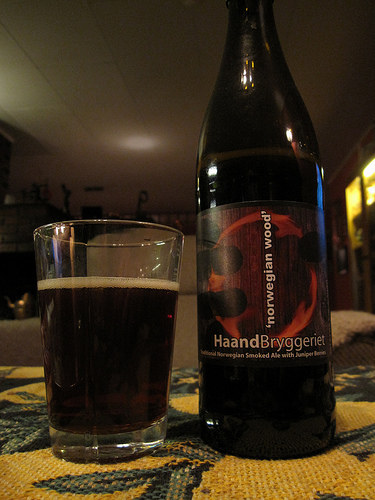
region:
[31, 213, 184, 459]
Clear glass full of ale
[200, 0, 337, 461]
bottle of Norwegian ale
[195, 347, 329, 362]
Traditional Norwegian smoked ale with juniper berries on bottle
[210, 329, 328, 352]
HaandBryggeriet on side of bottle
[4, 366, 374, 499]
floral design on table cover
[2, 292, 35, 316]
tea kettle in background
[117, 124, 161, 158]
glare of light on ceiling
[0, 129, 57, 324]
fireplace in the background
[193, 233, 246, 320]
berry design on bottle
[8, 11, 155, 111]
white ceiling tiles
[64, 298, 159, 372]
Brown liquid in glass.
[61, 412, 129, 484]
Glass sitting on yellow place mat.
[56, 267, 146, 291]
White head on beer.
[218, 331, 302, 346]
White writing on bottle.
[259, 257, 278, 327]
White writing on bottle.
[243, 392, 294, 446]
Dark colored bottle on table.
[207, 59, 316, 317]
Large dark bottle sitting on table.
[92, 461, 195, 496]
Blue coloring on yellow place mat.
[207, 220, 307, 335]
Red coloring on bottle label.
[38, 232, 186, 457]
Clear glass sitting on table.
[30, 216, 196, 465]
dark liquid in a glass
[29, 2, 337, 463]
dark bottle next to the glass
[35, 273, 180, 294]
foam on top of the liquid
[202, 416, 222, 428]
light glare on the bottle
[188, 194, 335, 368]
label around the bottle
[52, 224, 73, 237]
light glare on the glass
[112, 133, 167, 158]
light shining on the ceiling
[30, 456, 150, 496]
blue leaf on a yellow background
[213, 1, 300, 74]
neck of the bottle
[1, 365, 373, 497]
yellow and blue pattern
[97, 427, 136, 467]
edge fo a base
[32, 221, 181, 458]
A glass on the table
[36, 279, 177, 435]
Ale in the cup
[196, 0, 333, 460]
A bottle of ale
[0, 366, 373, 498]
A table beneath the ale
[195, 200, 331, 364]
A label on the ale bottle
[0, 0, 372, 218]
The ceiling above the ale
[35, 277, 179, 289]
Foam at the top of the ale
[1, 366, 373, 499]
The table has a cloth on it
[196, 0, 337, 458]
The bottle contains ale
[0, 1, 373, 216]
The ceiling in the room